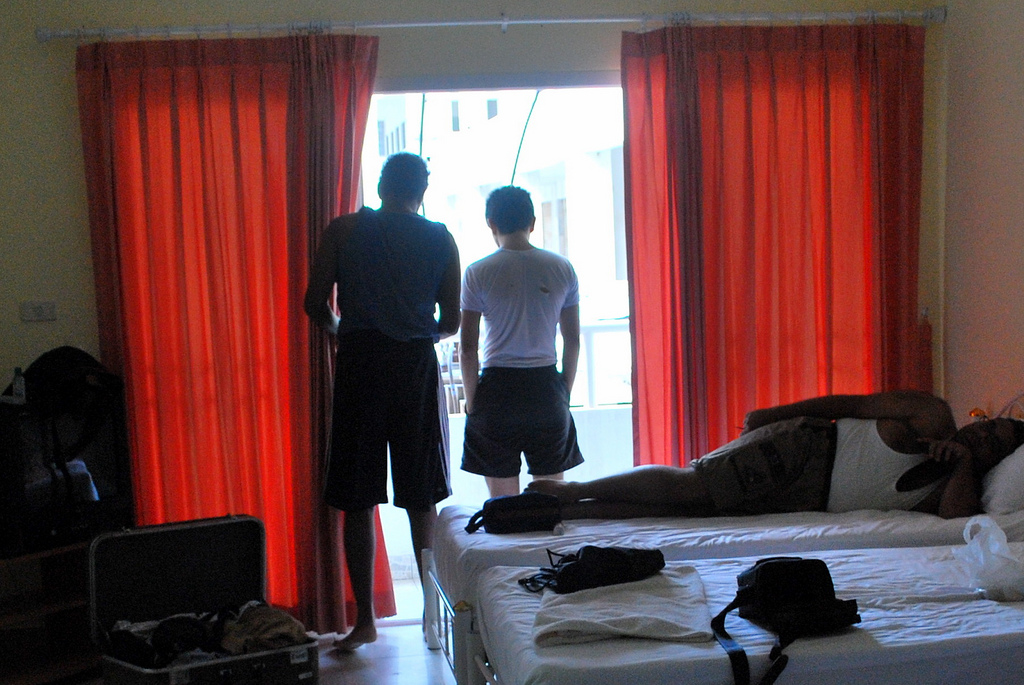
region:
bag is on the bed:
[730, 538, 874, 672]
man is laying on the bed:
[519, 399, 1017, 537]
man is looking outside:
[452, 182, 582, 492]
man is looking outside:
[303, 147, 471, 672]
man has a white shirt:
[464, 248, 582, 378]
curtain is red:
[85, 15, 399, 629]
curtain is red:
[637, 13, 928, 463]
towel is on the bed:
[520, 544, 724, 668]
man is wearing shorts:
[452, 361, 589, 478]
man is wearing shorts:
[315, 337, 461, 509]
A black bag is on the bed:
[684, 511, 995, 667]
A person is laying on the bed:
[413, 376, 1021, 542]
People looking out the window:
[272, 19, 640, 648]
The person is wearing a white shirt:
[422, 167, 607, 402]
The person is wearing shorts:
[419, 154, 667, 541]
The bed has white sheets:
[373, 420, 1006, 563]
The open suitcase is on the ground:
[77, 481, 387, 677]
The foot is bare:
[286, 515, 423, 683]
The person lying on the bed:
[548, 382, 991, 509]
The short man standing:
[461, 165, 639, 486]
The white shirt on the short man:
[454, 247, 585, 362]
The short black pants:
[459, 365, 611, 477]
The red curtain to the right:
[596, 26, 977, 441]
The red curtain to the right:
[58, 30, 412, 654]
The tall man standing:
[303, 118, 494, 650]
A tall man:
[315, 140, 502, 647]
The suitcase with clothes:
[65, 512, 323, 658]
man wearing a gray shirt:
[331, 200, 453, 340]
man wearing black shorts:
[328, 331, 453, 525]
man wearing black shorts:
[449, 364, 590, 472]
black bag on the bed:
[686, 535, 842, 682]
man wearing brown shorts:
[701, 398, 832, 515]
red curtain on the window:
[623, 18, 950, 430]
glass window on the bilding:
[373, 87, 409, 161]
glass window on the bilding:
[535, 191, 548, 253]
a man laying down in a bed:
[520, 383, 1020, 524]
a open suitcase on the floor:
[89, 522, 337, 682]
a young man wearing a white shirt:
[472, 247, 577, 364]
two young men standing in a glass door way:
[308, 143, 597, 466]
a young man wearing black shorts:
[469, 349, 580, 474]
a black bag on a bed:
[733, 542, 863, 656]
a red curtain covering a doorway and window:
[608, 3, 903, 444]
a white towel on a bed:
[535, 583, 709, 644]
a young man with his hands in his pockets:
[459, 343, 583, 435]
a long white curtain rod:
[32, 3, 940, 51]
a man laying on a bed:
[522, 379, 1020, 528]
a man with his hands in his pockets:
[453, 183, 583, 482]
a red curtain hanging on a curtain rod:
[614, 7, 932, 469]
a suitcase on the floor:
[79, 525, 336, 682]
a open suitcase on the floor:
[71, 519, 315, 682]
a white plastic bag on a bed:
[942, 506, 1018, 606]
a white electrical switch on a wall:
[16, 292, 58, 327]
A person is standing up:
[471, 190, 580, 484]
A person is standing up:
[322, 159, 458, 647]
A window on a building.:
[600, 141, 623, 282]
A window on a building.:
[555, 193, 566, 251]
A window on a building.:
[530, 196, 549, 253]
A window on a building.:
[486, 92, 496, 118]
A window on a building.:
[451, 96, 470, 125]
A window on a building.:
[401, 119, 408, 148]